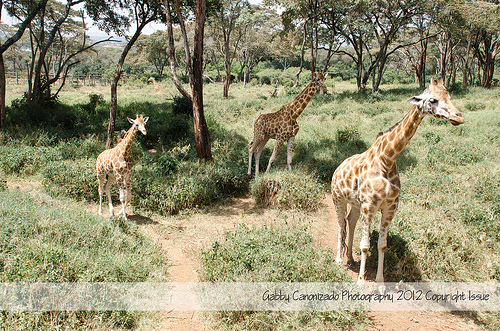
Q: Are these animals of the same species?
A: Yes, all the animals are giraffes.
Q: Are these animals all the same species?
A: Yes, all the animals are giraffes.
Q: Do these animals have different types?
A: No, all the animals are giraffes.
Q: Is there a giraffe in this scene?
A: Yes, there is a giraffe.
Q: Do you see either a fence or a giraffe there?
A: Yes, there is a giraffe.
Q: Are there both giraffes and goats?
A: No, there is a giraffe but no goats.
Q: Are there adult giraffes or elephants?
A: Yes, there is an adult giraffe.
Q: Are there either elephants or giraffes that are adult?
A: Yes, the giraffe is adult.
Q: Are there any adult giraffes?
A: Yes, there is an adult giraffe.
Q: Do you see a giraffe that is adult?
A: Yes, there is a giraffe that is adult.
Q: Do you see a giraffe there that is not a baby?
A: Yes, there is a adult giraffe.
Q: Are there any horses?
A: No, there are no horses.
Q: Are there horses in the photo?
A: No, there are no horses.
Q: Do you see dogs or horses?
A: No, there are no horses or dogs.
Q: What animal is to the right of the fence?
A: The animal is a giraffe.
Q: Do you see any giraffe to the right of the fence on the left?
A: Yes, there is a giraffe to the right of the fence.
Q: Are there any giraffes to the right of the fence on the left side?
A: Yes, there is a giraffe to the right of the fence.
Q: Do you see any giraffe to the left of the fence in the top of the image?
A: No, the giraffe is to the right of the fence.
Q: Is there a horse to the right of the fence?
A: No, there is a giraffe to the right of the fence.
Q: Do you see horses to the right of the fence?
A: No, there is a giraffe to the right of the fence.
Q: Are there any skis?
A: No, there are no skis.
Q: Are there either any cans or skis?
A: No, there are no skis or cans.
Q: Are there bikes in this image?
A: No, there are no bikes.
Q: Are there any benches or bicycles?
A: No, there are no bicycles or benches.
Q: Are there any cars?
A: No, there are no cars.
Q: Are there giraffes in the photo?
A: Yes, there is a giraffe.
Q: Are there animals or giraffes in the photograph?
A: Yes, there is a giraffe.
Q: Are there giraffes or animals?
A: Yes, there is a giraffe.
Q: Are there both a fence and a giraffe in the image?
A: Yes, there are both a giraffe and a fence.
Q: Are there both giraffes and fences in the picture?
A: Yes, there are both a giraffe and a fence.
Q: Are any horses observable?
A: No, there are no horses.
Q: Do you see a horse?
A: No, there are no horses.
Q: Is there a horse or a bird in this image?
A: No, there are no horses or birds.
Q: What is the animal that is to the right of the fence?
A: The animal is a giraffe.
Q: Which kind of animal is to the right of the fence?
A: The animal is a giraffe.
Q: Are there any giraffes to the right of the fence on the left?
A: Yes, there is a giraffe to the right of the fence.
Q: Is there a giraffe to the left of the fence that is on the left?
A: No, the giraffe is to the right of the fence.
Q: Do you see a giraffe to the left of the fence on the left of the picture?
A: No, the giraffe is to the right of the fence.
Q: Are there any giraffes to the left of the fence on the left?
A: No, the giraffe is to the right of the fence.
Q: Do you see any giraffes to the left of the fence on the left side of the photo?
A: No, the giraffe is to the right of the fence.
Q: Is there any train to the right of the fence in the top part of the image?
A: No, there is a giraffe to the right of the fence.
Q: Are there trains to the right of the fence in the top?
A: No, there is a giraffe to the right of the fence.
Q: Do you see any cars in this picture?
A: No, there are no cars.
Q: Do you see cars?
A: No, there are no cars.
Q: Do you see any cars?
A: No, there are no cars.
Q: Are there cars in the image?
A: No, there are no cars.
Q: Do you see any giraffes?
A: Yes, there is a giraffe.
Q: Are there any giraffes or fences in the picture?
A: Yes, there is a giraffe.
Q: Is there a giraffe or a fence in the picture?
A: Yes, there is a giraffe.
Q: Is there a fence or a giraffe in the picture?
A: Yes, there is a giraffe.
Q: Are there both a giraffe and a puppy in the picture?
A: No, there is a giraffe but no puppys.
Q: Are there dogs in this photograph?
A: No, there are no dogs.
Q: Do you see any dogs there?
A: No, there are no dogs.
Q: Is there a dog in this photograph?
A: No, there are no dogs.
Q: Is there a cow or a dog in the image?
A: No, there are no dogs or cows.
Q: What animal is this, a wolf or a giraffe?
A: This is a giraffe.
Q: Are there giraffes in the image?
A: Yes, there is a giraffe.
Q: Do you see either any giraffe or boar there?
A: Yes, there is a giraffe.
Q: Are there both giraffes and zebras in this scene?
A: No, there is a giraffe but no zebras.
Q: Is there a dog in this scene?
A: No, there are no dogs.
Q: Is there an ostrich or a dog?
A: No, there are no dogs or ostriches.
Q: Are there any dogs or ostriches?
A: No, there are no dogs or ostriches.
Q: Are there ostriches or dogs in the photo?
A: No, there are no dogs or ostriches.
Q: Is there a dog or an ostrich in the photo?
A: No, there are no dogs or ostriches.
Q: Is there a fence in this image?
A: Yes, there is a fence.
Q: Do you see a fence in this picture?
A: Yes, there is a fence.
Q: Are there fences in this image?
A: Yes, there is a fence.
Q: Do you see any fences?
A: Yes, there is a fence.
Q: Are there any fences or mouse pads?
A: Yes, there is a fence.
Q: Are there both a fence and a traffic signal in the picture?
A: No, there is a fence but no traffic lights.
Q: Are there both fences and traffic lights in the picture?
A: No, there is a fence but no traffic lights.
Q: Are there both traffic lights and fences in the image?
A: No, there is a fence but no traffic lights.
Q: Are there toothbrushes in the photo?
A: No, there are no toothbrushes.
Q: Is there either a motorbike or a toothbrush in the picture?
A: No, there are no toothbrushes or motorcycles.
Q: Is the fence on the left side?
A: Yes, the fence is on the left of the image.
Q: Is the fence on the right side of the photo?
A: No, the fence is on the left of the image.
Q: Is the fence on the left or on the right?
A: The fence is on the left of the image.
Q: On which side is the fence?
A: The fence is on the left of the image.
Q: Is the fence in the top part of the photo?
A: Yes, the fence is in the top of the image.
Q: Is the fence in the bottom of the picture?
A: No, the fence is in the top of the image.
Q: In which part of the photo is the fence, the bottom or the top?
A: The fence is in the top of the image.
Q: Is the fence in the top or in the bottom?
A: The fence is in the top of the image.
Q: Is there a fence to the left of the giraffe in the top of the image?
A: Yes, there is a fence to the left of the giraffe.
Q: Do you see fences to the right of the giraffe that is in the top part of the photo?
A: No, the fence is to the left of the giraffe.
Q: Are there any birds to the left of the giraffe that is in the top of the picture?
A: No, there is a fence to the left of the giraffe.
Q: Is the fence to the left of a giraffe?
A: Yes, the fence is to the left of a giraffe.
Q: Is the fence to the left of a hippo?
A: No, the fence is to the left of a giraffe.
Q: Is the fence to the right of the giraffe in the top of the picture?
A: No, the fence is to the left of the giraffe.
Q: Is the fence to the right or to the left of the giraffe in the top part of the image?
A: The fence is to the left of the giraffe.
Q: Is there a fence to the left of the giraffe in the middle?
A: Yes, there is a fence to the left of the giraffe.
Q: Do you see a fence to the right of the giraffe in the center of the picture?
A: No, the fence is to the left of the giraffe.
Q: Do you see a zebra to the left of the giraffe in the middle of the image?
A: No, there is a fence to the left of the giraffe.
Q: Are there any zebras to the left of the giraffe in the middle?
A: No, there is a fence to the left of the giraffe.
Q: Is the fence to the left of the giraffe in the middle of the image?
A: Yes, the fence is to the left of the giraffe.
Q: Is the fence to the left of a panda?
A: No, the fence is to the left of the giraffe.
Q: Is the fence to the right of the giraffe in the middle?
A: No, the fence is to the left of the giraffe.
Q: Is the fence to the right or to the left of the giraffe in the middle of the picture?
A: The fence is to the left of the giraffe.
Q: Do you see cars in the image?
A: No, there are no cars.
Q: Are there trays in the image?
A: No, there are no trays.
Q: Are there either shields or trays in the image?
A: No, there are no trays or shields.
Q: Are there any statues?
A: No, there are no statues.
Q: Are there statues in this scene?
A: No, there are no statues.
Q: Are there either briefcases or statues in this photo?
A: No, there are no statues or briefcases.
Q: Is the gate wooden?
A: Yes, the gate is wooden.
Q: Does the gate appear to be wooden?
A: Yes, the gate is wooden.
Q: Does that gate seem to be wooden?
A: Yes, the gate is wooden.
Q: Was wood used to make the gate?
A: Yes, the gate is made of wood.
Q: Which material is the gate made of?
A: The gate is made of wood.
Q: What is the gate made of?
A: The gate is made of wood.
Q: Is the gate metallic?
A: No, the gate is wooden.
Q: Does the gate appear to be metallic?
A: No, the gate is wooden.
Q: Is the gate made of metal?
A: No, the gate is made of wood.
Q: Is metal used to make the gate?
A: No, the gate is made of wood.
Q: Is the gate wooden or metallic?
A: The gate is wooden.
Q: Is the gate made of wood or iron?
A: The gate is made of wood.